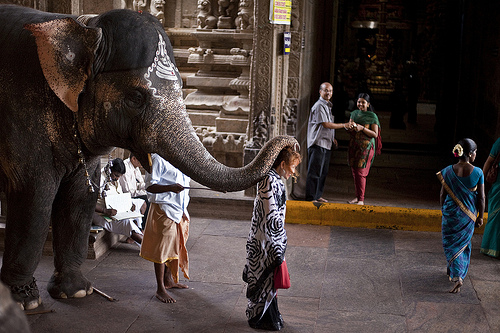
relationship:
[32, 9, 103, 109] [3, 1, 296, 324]
ear on elephant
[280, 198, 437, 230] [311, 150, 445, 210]
line on sidewalk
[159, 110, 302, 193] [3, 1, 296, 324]
trunk on elephant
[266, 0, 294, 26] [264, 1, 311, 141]
sign on wall